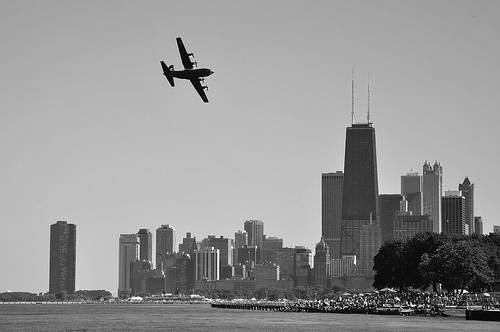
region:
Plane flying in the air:
[155, 31, 216, 108]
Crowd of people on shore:
[285, 285, 497, 315]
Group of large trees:
[370, 225, 496, 303]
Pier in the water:
[205, 300, 300, 313]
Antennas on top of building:
[345, 65, 376, 140]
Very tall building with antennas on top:
[335, 63, 382, 288]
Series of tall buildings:
[106, 215, 332, 303]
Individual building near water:
[41, 215, 86, 308]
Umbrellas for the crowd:
[336, 281, 402, 294]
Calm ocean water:
[1, 305, 286, 330]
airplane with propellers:
[135, 25, 238, 122]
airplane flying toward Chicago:
[28, 23, 482, 316]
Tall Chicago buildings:
[308, 56, 487, 302]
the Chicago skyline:
[13, 63, 484, 305]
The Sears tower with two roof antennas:
[327, 58, 389, 316]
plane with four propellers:
[118, 21, 244, 123]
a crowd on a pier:
[205, 267, 499, 326]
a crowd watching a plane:
[129, 29, 484, 318]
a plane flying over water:
[70, 22, 329, 325]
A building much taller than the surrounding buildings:
[237, 61, 391, 310]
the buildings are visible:
[187, 187, 436, 329]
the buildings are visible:
[205, 204, 314, 296]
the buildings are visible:
[240, 203, 331, 319]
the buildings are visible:
[227, 177, 307, 265]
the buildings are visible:
[224, 131, 306, 302]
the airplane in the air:
[150, 23, 226, 120]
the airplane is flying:
[150, 17, 250, 127]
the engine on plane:
[166, 45, 218, 90]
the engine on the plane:
[180, 50, 220, 90]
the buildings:
[125, 197, 496, 294]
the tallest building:
[340, 57, 420, 302]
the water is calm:
[108, 308, 243, 323]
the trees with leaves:
[376, 240, 499, 275]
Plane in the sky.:
[135, 27, 234, 109]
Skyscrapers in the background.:
[282, 95, 428, 265]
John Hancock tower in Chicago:
[326, 52, 454, 261]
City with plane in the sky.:
[65, 31, 466, 305]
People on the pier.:
[194, 275, 369, 329]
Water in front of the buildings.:
[47, 281, 119, 328]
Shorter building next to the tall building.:
[108, 55, 479, 309]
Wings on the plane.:
[141, 24, 241, 125]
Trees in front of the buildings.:
[376, 199, 496, 311]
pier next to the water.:
[207, 270, 370, 320]